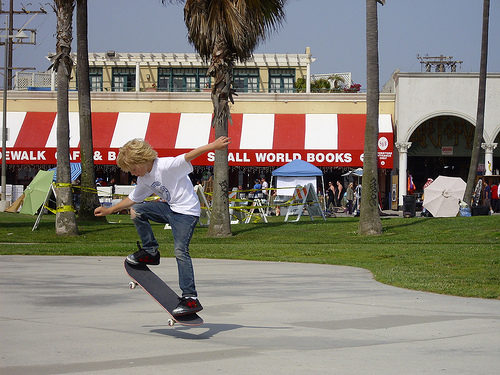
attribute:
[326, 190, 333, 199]
shirt — black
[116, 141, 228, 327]
kid — skateboarding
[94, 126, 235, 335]
boy — skateboarding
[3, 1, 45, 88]
pole — electrical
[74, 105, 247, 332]
boy — young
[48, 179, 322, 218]
tape — yellow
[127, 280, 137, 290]
wheel — white, red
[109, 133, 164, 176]
hair — blonde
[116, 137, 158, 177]
blonde hair — long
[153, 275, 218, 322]
sneaker — red, black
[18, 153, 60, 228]
umbrella — green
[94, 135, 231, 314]
boy — young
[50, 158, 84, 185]
umbrella — striped, white, blue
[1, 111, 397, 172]
canopy — striped, white, red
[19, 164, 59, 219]
umbrella — green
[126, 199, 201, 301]
jeans — blue, pair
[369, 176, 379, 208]
graffiti — black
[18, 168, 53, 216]
parasol — green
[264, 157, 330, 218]
canopy — blue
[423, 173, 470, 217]
parasol — white